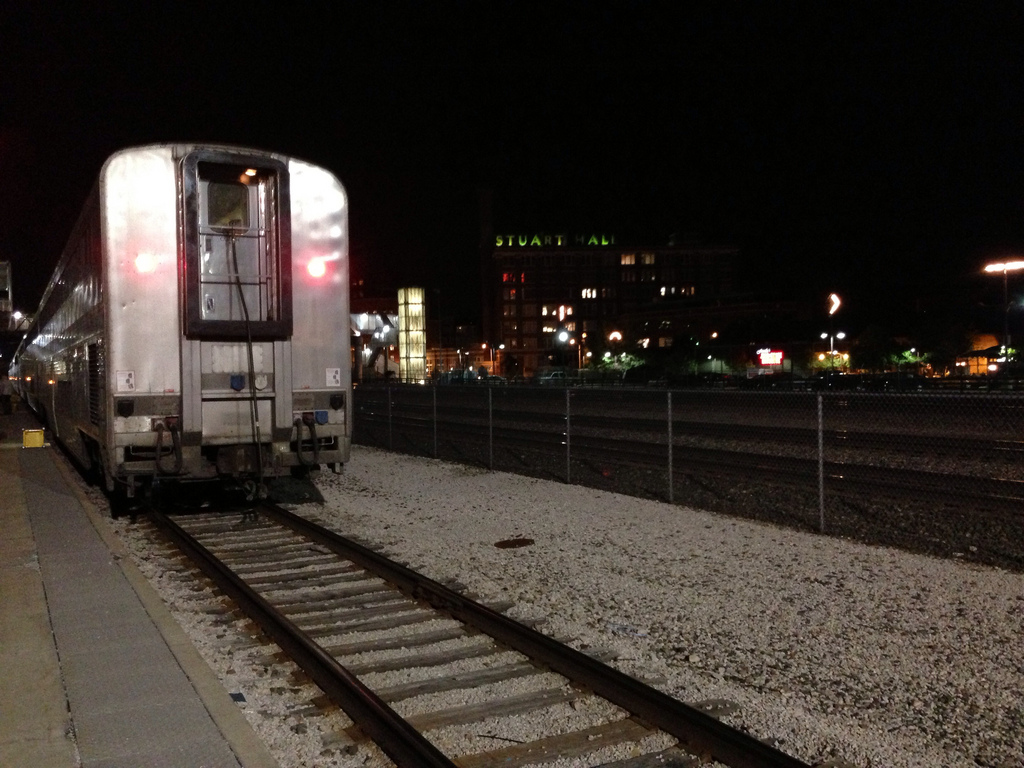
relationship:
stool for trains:
[16, 421, 51, 454] [74, 127, 384, 501]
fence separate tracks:
[355, 376, 1022, 592] [277, 362, 1021, 762]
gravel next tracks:
[74, 449, 1021, 766] [40, 416, 1021, 730]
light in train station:
[392, 276, 435, 393] [353, 244, 535, 437]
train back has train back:
[39, 139, 356, 522] [101, 145, 356, 522]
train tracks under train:
[101, 504, 847, 765] [85, 131, 373, 499]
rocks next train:
[74, 443, 1021, 766] [42, 131, 380, 505]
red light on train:
[113, 229, 180, 302] [85, 131, 373, 499]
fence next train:
[355, 376, 1022, 592] [85, 131, 373, 499]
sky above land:
[0, 0, 1022, 367] [379, 388, 1017, 719]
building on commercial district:
[472, 209, 735, 381] [351, 215, 1021, 392]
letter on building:
[484, 229, 627, 249] [473, 180, 715, 368]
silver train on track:
[19, 144, 352, 503] [130, 507, 884, 735]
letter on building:
[484, 222, 628, 249] [487, 226, 722, 383]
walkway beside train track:
[3, 379, 280, 762] [187, 504, 810, 752]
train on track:
[23, 125, 374, 512] [164, 509, 856, 762]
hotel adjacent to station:
[475, 219, 763, 384] [4, 341, 998, 763]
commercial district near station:
[351, 215, 1020, 392] [0, 112, 1003, 763]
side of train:
[8, 192, 121, 484] [23, 125, 374, 512]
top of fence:
[330, 347, 1020, 441] [354, 345, 1022, 575]